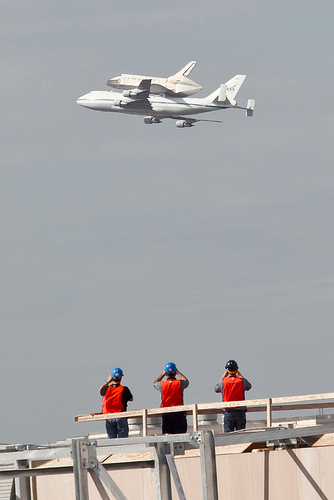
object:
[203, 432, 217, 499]
post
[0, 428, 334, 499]
surface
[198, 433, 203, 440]
stud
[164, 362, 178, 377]
helmet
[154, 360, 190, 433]
man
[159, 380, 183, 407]
shirt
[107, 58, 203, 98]
space shuttle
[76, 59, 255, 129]
jumbo jet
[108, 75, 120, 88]
nose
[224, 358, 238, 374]
hardhat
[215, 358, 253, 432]
man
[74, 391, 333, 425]
railing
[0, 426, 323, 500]
structure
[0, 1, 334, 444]
sky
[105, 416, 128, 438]
jeans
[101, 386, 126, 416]
vest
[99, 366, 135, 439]
man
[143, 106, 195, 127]
landing gear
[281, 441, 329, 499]
shadow